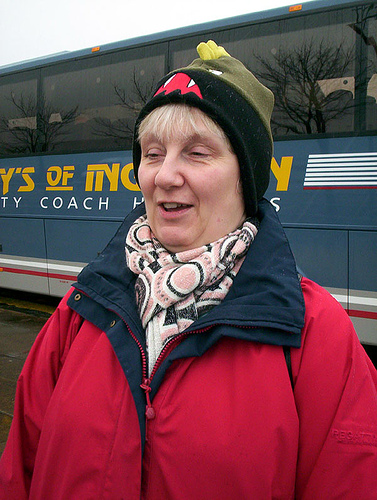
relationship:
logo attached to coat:
[326, 422, 376, 452] [12, 223, 372, 490]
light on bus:
[89, 43, 100, 51] [0, 2, 372, 305]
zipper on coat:
[75, 288, 259, 390] [180, 390, 262, 436]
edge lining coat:
[64, 287, 146, 498] [0, 196, 377, 500]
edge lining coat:
[279, 347, 300, 497] [0, 196, 377, 500]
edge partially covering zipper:
[64, 287, 146, 498] [72, 285, 263, 392]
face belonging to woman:
[137, 105, 240, 247] [1, 37, 364, 494]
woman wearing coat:
[1, 37, 364, 494] [0, 196, 377, 500]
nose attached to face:
[153, 144, 185, 190] [137, 105, 240, 247]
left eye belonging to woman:
[183, 146, 212, 160] [1, 37, 364, 494]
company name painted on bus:
[1, 155, 293, 194] [1, 1, 364, 343]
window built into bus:
[168, 5, 359, 137] [1, 1, 364, 343]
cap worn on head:
[132, 38, 275, 215] [135, 104, 250, 252]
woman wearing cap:
[1, 37, 364, 494] [132, 38, 275, 215]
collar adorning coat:
[65, 195, 307, 394] [0, 196, 377, 500]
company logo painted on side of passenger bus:
[0, 155, 294, 212] [1, 0, 364, 342]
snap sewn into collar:
[72, 292, 81, 301] [65, 195, 307, 408]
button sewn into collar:
[109, 320, 115, 328] [65, 195, 307, 408]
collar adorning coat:
[65, 195, 307, 408] [0, 196, 364, 496]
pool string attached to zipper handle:
[142, 383, 155, 420] [140, 382, 152, 390]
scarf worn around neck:
[123, 211, 260, 378] [154, 216, 248, 254]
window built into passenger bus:
[40, 40, 168, 153] [1, 0, 364, 342]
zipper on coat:
[118, 320, 218, 420] [0, 196, 364, 496]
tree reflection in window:
[0, 86, 82, 156] [168, 5, 359, 137]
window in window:
[168, 5, 359, 137] [40, 40, 168, 153]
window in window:
[40, 40, 168, 153] [0, 76, 38, 154]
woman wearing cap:
[1, 37, 364, 494] [132, 37, 278, 220]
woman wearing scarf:
[1, 37, 364, 494] [123, 211, 260, 378]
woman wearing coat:
[1, 37, 364, 494] [0, 196, 364, 496]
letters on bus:
[1, 152, 294, 193] [1, 1, 364, 343]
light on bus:
[284, 0, 305, 14] [1, 1, 364, 343]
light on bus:
[92, 46, 100, 51] [1, 1, 364, 343]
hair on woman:
[132, 104, 224, 143] [1, 37, 364, 494]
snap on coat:
[74, 294, 80, 301] [0, 196, 364, 496]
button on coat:
[104, 316, 119, 326] [0, 196, 364, 496]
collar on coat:
[65, 195, 307, 394] [0, 196, 364, 496]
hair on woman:
[138, 104, 225, 143] [1, 37, 364, 494]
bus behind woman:
[1, 1, 364, 343] [1, 37, 364, 494]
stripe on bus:
[0, 261, 376, 319] [1, 1, 364, 343]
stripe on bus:
[1, 261, 376, 323] [1, 1, 364, 343]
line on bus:
[0, 290, 59, 316] [1, 1, 364, 343]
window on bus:
[362, 13, 375, 138] [1, 1, 364, 343]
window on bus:
[168, 5, 359, 137] [1, 1, 364, 343]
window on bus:
[40, 40, 168, 153] [1, 1, 364, 343]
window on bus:
[0, 74, 35, 154] [1, 1, 364, 343]